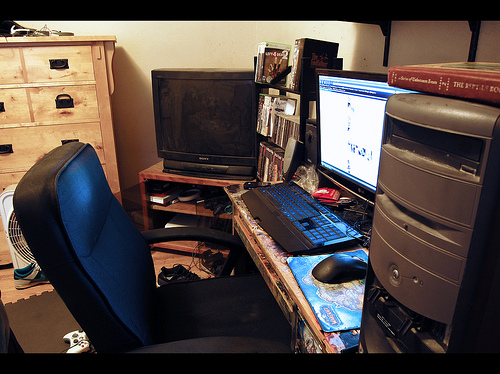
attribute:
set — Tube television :
[146, 67, 259, 172]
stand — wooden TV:
[132, 166, 243, 245]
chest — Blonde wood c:
[4, 31, 138, 210]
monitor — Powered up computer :
[305, 67, 391, 211]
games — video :
[151, 191, 178, 204]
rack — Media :
[140, 196, 229, 241]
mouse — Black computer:
[315, 250, 362, 285]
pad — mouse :
[294, 242, 362, 324]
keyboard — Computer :
[265, 180, 359, 255]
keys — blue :
[265, 186, 306, 220]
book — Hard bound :
[313, 185, 338, 201]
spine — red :
[306, 193, 337, 202]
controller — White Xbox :
[58, 325, 89, 355]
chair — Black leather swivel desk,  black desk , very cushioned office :
[13, 142, 302, 358]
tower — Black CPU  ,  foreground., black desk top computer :
[356, 87, 484, 356]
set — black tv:
[149, 63, 266, 181]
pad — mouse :
[288, 245, 367, 337]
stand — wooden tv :
[130, 160, 240, 254]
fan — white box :
[3, 184, 41, 282]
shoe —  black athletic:
[155, 262, 204, 282]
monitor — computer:
[308, 70, 402, 209]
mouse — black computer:
[314, 251, 369, 288]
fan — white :
[3, 190, 38, 289]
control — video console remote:
[55, 330, 85, 351]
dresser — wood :
[3, 32, 124, 200]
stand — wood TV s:
[131, 159, 245, 240]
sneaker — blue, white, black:
[12, 261, 52, 295]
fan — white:
[0, 176, 40, 298]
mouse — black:
[309, 241, 367, 283]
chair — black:
[9, 132, 310, 370]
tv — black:
[151, 62, 269, 186]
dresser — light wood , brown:
[2, 37, 137, 222]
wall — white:
[0, 14, 497, 195]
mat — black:
[3, 284, 93, 366]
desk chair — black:
[13, 143, 299, 372]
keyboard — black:
[238, 175, 368, 263]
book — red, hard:
[383, 48, 497, 106]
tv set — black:
[149, 63, 269, 183]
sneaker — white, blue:
[6, 255, 64, 295]